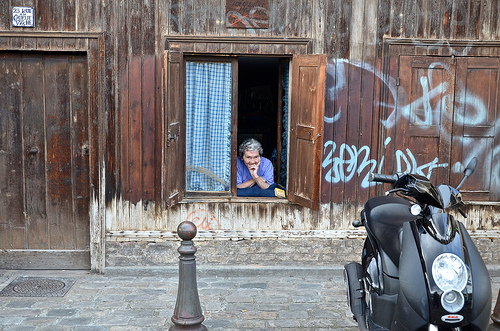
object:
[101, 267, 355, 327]
ground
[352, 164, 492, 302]
vehicle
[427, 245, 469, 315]
lights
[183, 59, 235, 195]
curtain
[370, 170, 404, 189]
handlebar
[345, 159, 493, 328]
bike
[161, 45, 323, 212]
window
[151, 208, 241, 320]
pole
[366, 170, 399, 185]
grip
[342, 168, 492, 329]
scooter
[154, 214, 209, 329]
post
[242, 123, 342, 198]
person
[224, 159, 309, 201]
shirt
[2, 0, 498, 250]
building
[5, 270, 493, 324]
sidewalk